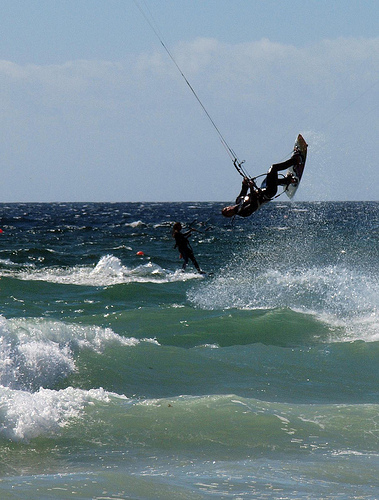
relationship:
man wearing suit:
[162, 217, 212, 286] [171, 233, 199, 271]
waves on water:
[321, 209, 353, 242] [5, 200, 376, 491]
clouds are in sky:
[0, 35, 377, 200] [3, 5, 361, 205]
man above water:
[169, 217, 212, 278] [60, 268, 338, 322]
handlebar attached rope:
[240, 176, 266, 192] [122, 12, 253, 186]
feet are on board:
[284, 141, 299, 189] [283, 119, 323, 208]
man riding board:
[169, 217, 212, 278] [163, 256, 224, 278]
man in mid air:
[217, 132, 308, 222] [0, 127, 378, 221]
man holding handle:
[169, 217, 212, 278] [185, 219, 212, 233]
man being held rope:
[217, 132, 308, 222] [122, 12, 253, 186]